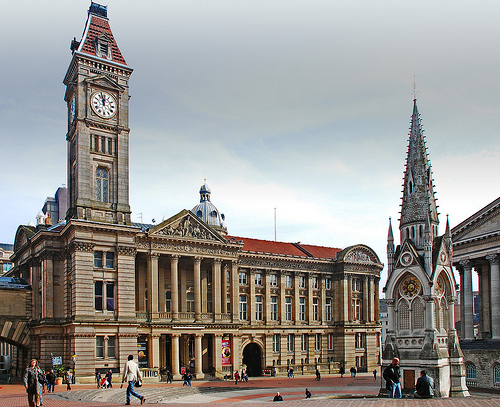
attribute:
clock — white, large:
[89, 80, 122, 116]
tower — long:
[55, 0, 133, 218]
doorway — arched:
[235, 338, 262, 378]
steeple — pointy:
[402, 118, 440, 234]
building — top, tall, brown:
[387, 225, 454, 360]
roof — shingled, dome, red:
[211, 230, 314, 256]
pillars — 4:
[123, 254, 241, 319]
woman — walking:
[20, 346, 48, 397]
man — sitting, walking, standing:
[415, 370, 437, 396]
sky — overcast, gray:
[202, 5, 226, 22]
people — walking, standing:
[15, 357, 74, 393]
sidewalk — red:
[278, 383, 290, 387]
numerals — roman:
[87, 102, 97, 114]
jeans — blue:
[129, 389, 141, 398]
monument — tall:
[398, 303, 447, 364]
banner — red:
[218, 337, 235, 367]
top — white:
[127, 365, 139, 378]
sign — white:
[132, 341, 148, 358]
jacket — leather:
[28, 371, 38, 386]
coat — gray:
[122, 357, 141, 379]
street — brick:
[141, 390, 174, 399]